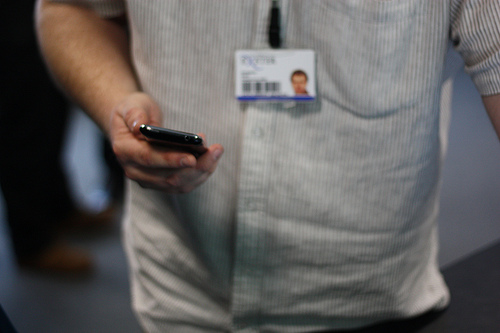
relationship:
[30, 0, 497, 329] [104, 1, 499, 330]
worker wearing shirt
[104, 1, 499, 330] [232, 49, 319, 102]
shirt with id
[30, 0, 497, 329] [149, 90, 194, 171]
worker using phone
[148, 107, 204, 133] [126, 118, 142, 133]
reflection off thumbnail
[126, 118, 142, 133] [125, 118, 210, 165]
thumbnail on top of cellphone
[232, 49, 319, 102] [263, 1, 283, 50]
id on lanyard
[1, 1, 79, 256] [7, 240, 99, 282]
slacks and brown shoe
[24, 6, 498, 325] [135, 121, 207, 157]
guy messing with cellphone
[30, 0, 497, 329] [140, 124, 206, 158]
worker making call on phone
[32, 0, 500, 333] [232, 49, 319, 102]
guy has id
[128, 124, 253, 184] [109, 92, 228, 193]
cellphone held in hand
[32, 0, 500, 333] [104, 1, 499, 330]
guy wearing shirt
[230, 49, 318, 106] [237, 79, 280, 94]
id has barcode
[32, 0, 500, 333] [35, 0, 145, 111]
guy has arm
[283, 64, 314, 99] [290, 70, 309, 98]
picture of face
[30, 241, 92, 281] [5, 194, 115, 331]
brown shoe in background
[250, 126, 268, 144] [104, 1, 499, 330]
button on shirt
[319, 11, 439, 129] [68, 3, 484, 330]
pocket on shirt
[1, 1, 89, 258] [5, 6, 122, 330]
slacks in background